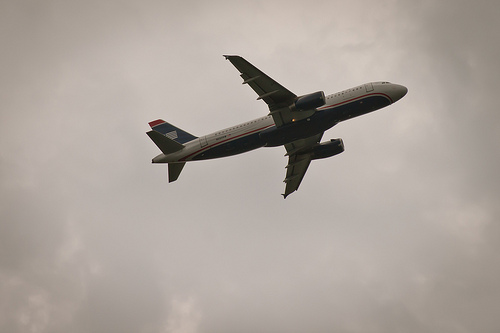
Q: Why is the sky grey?
A: Overcast.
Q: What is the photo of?
A: A plane.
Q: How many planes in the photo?
A: One.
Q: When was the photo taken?
A: Daytime.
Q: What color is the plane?
A: Grey.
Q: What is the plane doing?
A: Flying.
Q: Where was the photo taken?
A: From the ground underneath an airplane.